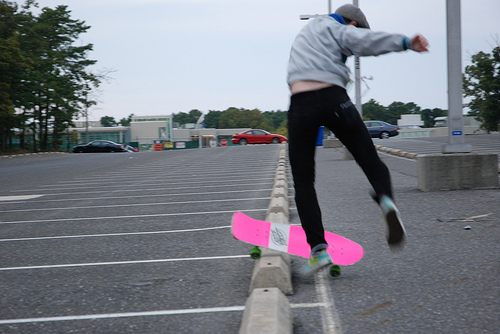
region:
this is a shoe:
[372, 195, 425, 262]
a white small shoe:
[271, 235, 361, 289]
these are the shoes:
[266, 185, 446, 305]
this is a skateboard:
[216, 190, 426, 307]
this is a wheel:
[230, 244, 275, 266]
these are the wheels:
[235, 245, 352, 297]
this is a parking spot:
[24, 175, 284, 197]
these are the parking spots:
[33, 131, 258, 331]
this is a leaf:
[88, 63, 95, 64]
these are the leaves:
[11, 40, 75, 99]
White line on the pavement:
[13, 280, 239, 325]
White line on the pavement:
[6, 254, 221, 282]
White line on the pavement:
[5, 229, 226, 247]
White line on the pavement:
[14, 205, 233, 226]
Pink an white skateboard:
[210, 191, 384, 288]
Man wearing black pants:
[268, 11, 442, 280]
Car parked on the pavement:
[225, 120, 286, 158]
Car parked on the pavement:
[57, 118, 144, 174]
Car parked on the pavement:
[340, 108, 407, 151]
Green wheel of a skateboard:
[243, 241, 264, 266]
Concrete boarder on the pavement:
[232, 279, 292, 332]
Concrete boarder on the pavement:
[243, 208, 288, 293]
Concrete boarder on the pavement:
[272, 183, 289, 195]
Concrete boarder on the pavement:
[270, 168, 287, 183]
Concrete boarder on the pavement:
[272, 137, 285, 161]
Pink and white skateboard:
[218, 193, 367, 303]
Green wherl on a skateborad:
[243, 240, 261, 260]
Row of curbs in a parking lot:
[265, 136, 300, 221]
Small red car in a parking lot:
[221, 120, 286, 150]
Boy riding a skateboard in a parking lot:
[225, 0, 425, 285]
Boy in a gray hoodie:
[271, 0, 436, 281]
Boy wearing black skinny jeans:
[275, 0, 420, 285]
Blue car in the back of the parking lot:
[64, 131, 132, 156]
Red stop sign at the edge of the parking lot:
[212, 133, 231, 149]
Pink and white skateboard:
[223, 204, 370, 292]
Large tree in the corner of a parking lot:
[2, 1, 117, 156]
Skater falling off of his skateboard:
[186, 5, 453, 305]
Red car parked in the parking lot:
[222, 115, 287, 151]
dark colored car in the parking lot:
[58, 132, 130, 164]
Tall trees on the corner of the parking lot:
[2, 1, 128, 168]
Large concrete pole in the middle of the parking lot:
[441, 0, 489, 190]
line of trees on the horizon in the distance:
[92, 98, 476, 158]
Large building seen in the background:
[50, 90, 239, 163]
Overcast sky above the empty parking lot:
[91, 8, 459, 110]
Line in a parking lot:
[100, 244, 192, 276]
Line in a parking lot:
[96, 294, 187, 327]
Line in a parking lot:
[93, 225, 165, 243]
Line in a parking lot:
[156, 197, 216, 209]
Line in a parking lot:
[79, 191, 132, 206]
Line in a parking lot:
[138, 299, 222, 322]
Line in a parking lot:
[128, 248, 225, 265]